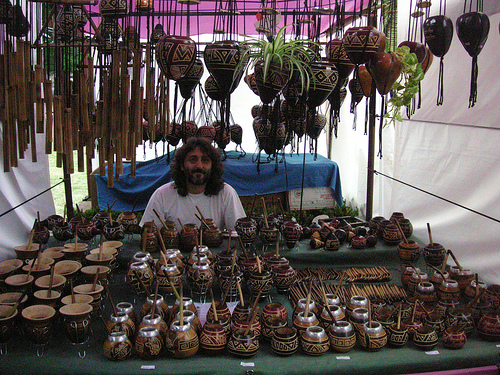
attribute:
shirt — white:
[146, 183, 249, 234]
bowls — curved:
[229, 301, 398, 361]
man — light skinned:
[139, 138, 246, 228]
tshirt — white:
[140, 188, 272, 228]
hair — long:
[170, 135, 225, 197]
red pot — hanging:
[362, 52, 402, 94]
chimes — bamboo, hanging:
[41, 40, 161, 187]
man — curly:
[129, 124, 249, 232]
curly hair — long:
[157, 130, 230, 190]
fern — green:
[230, 21, 327, 102]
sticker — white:
[331, 352, 356, 362]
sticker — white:
[421, 342, 444, 359]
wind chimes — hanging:
[103, 7, 434, 142]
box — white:
[285, 187, 337, 209]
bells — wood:
[1, 27, 175, 200]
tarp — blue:
[93, 141, 343, 209]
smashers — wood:
[292, 247, 414, 303]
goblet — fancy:
[59, 300, 93, 354]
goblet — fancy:
[18, 302, 56, 358]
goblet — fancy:
[79, 261, 111, 305]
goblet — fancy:
[0, 269, 36, 301]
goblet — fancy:
[86, 245, 116, 286]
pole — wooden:
[364, 86, 376, 226]